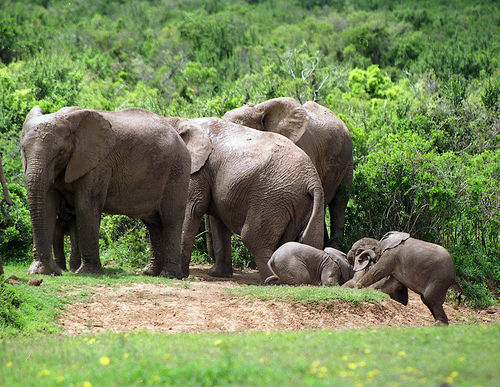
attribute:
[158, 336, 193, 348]
grass — green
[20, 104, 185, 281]
elephant — gray, grey, in herd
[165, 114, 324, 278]
elephant — grey, here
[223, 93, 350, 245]
elephant — grey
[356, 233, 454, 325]
elephant — baby, here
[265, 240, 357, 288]
elephant — baby, sitting, small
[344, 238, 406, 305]
elephant — playing, here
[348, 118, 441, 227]
tree — green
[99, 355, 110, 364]
flower — yellow